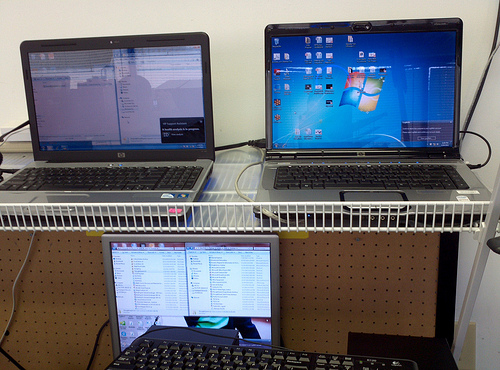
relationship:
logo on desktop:
[337, 66, 387, 117] [249, 15, 499, 218]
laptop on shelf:
[1, 31, 215, 221] [2, 152, 494, 234]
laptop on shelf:
[252, 16, 499, 221] [2, 152, 494, 234]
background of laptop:
[32, 52, 203, 144] [1, 31, 215, 221]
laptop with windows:
[1, 31, 215, 221] [111, 51, 205, 147]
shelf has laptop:
[2, 152, 494, 234] [1, 31, 215, 221]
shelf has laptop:
[2, 152, 494, 234] [252, 16, 499, 221]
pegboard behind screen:
[1, 221, 439, 369] [111, 240, 273, 354]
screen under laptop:
[111, 240, 273, 354] [1, 31, 215, 221]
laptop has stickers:
[1, 31, 215, 221] [160, 193, 187, 215]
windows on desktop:
[111, 51, 205, 147] [249, 15, 499, 218]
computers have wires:
[4, 18, 493, 360] [212, 139, 305, 228]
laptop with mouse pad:
[1, 31, 215, 221] [28, 194, 90, 210]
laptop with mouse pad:
[252, 16, 499, 221] [343, 190, 407, 214]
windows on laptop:
[111, 51, 205, 147] [1, 31, 215, 221]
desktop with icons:
[249, 15, 499, 218] [304, 36, 334, 105]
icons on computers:
[304, 36, 334, 105] [4, 18, 493, 360]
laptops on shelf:
[1, 18, 494, 217] [2, 152, 494, 234]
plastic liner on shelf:
[187, 154, 273, 227] [2, 152, 494, 234]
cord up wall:
[462, 2, 499, 169] [1, 3, 500, 185]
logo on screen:
[337, 66, 387, 117] [273, 36, 456, 147]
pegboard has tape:
[1, 221, 439, 369] [85, 225, 309, 239]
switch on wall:
[454, 321, 476, 369] [1, 3, 500, 185]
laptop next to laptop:
[1, 31, 215, 221] [252, 16, 499, 221]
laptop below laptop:
[102, 229, 281, 361] [1, 31, 215, 221]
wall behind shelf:
[1, 3, 500, 185] [2, 152, 494, 234]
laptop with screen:
[252, 16, 499, 221] [111, 240, 273, 354]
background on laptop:
[32, 52, 203, 144] [1, 31, 215, 221]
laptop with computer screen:
[1, 31, 215, 221] [111, 240, 273, 354]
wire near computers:
[2, 230, 110, 369] [4, 18, 493, 360]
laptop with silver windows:
[1, 31, 215, 221] [111, 51, 205, 147]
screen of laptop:
[111, 240, 273, 354] [102, 229, 281, 361]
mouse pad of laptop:
[28, 194, 90, 210] [1, 31, 215, 221]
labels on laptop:
[456, 188, 481, 206] [252, 16, 499, 221]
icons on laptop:
[304, 36, 334, 105] [252, 16, 499, 221]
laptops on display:
[1, 18, 494, 217] [3, 126, 499, 369]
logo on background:
[337, 66, 387, 117] [32, 52, 203, 144]